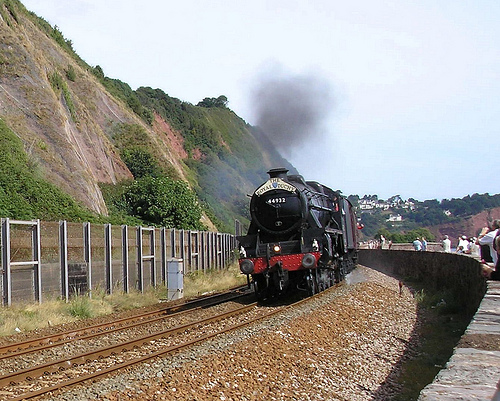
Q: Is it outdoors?
A: Yes, it is outdoors.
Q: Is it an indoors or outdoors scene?
A: It is outdoors.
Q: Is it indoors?
A: No, it is outdoors.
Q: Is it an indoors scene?
A: No, it is outdoors.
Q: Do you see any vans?
A: No, there are no vans.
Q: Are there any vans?
A: No, there are no vans.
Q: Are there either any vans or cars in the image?
A: No, there are no vans or cars.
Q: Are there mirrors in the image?
A: No, there are no mirrors.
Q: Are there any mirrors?
A: No, there are no mirrors.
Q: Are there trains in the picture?
A: Yes, there is a train.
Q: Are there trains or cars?
A: Yes, there is a train.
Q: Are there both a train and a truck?
A: No, there is a train but no trucks.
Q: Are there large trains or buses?
A: Yes, there is a large train.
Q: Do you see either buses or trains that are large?
A: Yes, the train is large.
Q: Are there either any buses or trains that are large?
A: Yes, the train is large.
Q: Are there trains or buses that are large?
A: Yes, the train is large.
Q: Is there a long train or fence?
A: Yes, there is a long train.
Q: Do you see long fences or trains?
A: Yes, there is a long train.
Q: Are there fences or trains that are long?
A: Yes, the train is long.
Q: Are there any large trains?
A: Yes, there is a large train.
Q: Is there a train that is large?
A: Yes, there is a train that is large.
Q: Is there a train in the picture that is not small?
A: Yes, there is a large train.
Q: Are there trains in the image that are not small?
A: Yes, there is a large train.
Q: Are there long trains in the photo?
A: Yes, there is a long train.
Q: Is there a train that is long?
A: Yes, there is a long train.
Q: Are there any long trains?
A: Yes, there is a long train.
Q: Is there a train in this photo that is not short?
A: Yes, there is a long train.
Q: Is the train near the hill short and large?
A: No, the train is large but long.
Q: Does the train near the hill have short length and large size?
A: No, the train is large but long.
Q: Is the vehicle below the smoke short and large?
A: No, the train is large but long.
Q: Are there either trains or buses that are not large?
A: No, there is a train but it is large.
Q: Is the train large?
A: Yes, the train is large.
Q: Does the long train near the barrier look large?
A: Yes, the train is large.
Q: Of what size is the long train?
A: The train is large.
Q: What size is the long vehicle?
A: The train is large.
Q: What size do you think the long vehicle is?
A: The train is large.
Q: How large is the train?
A: The train is large.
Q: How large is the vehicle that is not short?
A: The train is large.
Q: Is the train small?
A: No, the train is large.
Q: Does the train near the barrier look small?
A: No, the train is large.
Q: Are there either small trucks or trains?
A: No, there is a train but it is large.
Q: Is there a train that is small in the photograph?
A: No, there is a train but it is large.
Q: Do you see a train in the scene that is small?
A: No, there is a train but it is large.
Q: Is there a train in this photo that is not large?
A: No, there is a train but it is large.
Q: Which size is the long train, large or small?
A: The train is large.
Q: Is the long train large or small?
A: The train is large.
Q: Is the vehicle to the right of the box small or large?
A: The train is large.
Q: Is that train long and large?
A: Yes, the train is long and large.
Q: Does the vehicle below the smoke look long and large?
A: Yes, the train is long and large.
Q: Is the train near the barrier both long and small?
A: No, the train is long but large.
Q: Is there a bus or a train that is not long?
A: No, there is a train but it is long.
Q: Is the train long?
A: Yes, the train is long.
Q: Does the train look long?
A: Yes, the train is long.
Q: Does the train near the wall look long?
A: Yes, the train is long.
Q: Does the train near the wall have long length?
A: Yes, the train is long.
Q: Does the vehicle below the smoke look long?
A: Yes, the train is long.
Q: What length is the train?
A: The train is long.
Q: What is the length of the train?
A: The train is long.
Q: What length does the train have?
A: The train has long length.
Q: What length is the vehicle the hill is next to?
A: The train is long.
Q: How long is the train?
A: The train is long.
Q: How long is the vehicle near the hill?
A: The train is long.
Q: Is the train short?
A: No, the train is long.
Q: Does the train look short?
A: No, the train is long.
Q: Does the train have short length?
A: No, the train is long.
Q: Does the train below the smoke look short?
A: No, the train is long.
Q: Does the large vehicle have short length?
A: No, the train is long.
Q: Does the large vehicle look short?
A: No, the train is long.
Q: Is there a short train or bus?
A: No, there is a train but it is long.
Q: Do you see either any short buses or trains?
A: No, there is a train but it is long.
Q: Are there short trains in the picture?
A: No, there is a train but it is long.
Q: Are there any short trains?
A: No, there is a train but it is long.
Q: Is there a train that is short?
A: No, there is a train but it is long.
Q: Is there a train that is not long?
A: No, there is a train but it is long.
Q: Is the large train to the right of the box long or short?
A: The train is long.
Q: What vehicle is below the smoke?
A: The vehicle is a train.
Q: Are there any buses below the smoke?
A: No, there is a train below the smoke.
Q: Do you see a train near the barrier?
A: Yes, there is a train near the barrier.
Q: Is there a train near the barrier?
A: Yes, there is a train near the barrier.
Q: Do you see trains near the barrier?
A: Yes, there is a train near the barrier.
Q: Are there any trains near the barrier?
A: Yes, there is a train near the barrier.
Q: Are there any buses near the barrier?
A: No, there is a train near the barrier.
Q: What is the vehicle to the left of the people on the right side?
A: The vehicle is a train.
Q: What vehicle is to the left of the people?
A: The vehicle is a train.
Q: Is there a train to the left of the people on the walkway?
A: Yes, there is a train to the left of the people.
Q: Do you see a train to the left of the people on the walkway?
A: Yes, there is a train to the left of the people.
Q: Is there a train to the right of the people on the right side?
A: No, the train is to the left of the people.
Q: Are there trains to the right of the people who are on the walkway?
A: No, the train is to the left of the people.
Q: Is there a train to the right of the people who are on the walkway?
A: No, the train is to the left of the people.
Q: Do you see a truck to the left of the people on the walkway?
A: No, there is a train to the left of the people.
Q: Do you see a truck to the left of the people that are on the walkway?
A: No, there is a train to the left of the people.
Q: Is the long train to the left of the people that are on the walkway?
A: Yes, the train is to the left of the people.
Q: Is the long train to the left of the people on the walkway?
A: Yes, the train is to the left of the people.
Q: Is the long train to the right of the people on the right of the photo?
A: No, the train is to the left of the people.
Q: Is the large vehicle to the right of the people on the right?
A: No, the train is to the left of the people.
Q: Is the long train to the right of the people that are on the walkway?
A: No, the train is to the left of the people.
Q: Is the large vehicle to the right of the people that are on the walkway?
A: No, the train is to the left of the people.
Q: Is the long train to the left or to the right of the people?
A: The train is to the left of the people.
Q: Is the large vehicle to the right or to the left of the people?
A: The train is to the left of the people.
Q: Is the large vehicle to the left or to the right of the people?
A: The train is to the left of the people.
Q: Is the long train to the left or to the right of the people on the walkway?
A: The train is to the left of the people.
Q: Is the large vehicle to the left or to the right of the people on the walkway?
A: The train is to the left of the people.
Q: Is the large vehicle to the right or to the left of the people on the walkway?
A: The train is to the left of the people.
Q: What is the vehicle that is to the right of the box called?
A: The vehicle is a train.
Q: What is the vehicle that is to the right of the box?
A: The vehicle is a train.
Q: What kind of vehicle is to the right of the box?
A: The vehicle is a train.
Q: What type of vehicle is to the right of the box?
A: The vehicle is a train.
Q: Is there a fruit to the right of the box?
A: No, there is a train to the right of the box.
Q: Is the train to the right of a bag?
A: No, the train is to the right of the box.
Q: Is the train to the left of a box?
A: No, the train is to the right of a box.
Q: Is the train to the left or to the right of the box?
A: The train is to the right of the box.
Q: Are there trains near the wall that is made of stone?
A: Yes, there is a train near the wall.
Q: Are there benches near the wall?
A: No, there is a train near the wall.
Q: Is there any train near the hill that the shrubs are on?
A: Yes, there is a train near the hill.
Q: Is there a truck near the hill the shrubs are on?
A: No, there is a train near the hill.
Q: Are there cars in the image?
A: No, there are no cars.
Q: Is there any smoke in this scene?
A: Yes, there is smoke.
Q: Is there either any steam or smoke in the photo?
A: Yes, there is smoke.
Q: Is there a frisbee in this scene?
A: No, there are no frisbees.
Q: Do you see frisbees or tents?
A: No, there are no frisbees or tents.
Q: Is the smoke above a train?
A: Yes, the smoke is above a train.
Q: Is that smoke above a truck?
A: No, the smoke is above a train.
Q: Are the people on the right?
A: Yes, the people are on the right of the image.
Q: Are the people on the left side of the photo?
A: No, the people are on the right of the image.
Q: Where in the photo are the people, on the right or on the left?
A: The people are on the right of the image.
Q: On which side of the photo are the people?
A: The people are on the right of the image.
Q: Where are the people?
A: The people are on the walkway.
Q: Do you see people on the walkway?
A: Yes, there are people on the walkway.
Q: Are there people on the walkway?
A: Yes, there are people on the walkway.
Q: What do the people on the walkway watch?
A: The people watch the train.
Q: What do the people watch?
A: The people watch the train.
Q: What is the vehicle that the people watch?
A: The vehicle is a train.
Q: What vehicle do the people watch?
A: The people watch the train.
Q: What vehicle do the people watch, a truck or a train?
A: The people watch a train.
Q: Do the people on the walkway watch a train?
A: Yes, the people watch a train.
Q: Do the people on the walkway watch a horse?
A: No, the people watch a train.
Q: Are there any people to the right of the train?
A: Yes, there are people to the right of the train.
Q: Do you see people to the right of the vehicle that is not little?
A: Yes, there are people to the right of the train.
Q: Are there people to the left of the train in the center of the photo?
A: No, the people are to the right of the train.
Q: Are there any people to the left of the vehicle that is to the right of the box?
A: No, the people are to the right of the train.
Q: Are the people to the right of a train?
A: Yes, the people are to the right of a train.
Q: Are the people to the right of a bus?
A: No, the people are to the right of a train.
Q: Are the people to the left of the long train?
A: No, the people are to the right of the train.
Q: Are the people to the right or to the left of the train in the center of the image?
A: The people are to the right of the train.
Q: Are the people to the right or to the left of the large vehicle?
A: The people are to the right of the train.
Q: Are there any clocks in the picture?
A: No, there are no clocks.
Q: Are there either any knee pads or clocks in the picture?
A: No, there are no clocks or knee pads.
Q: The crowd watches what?
A: The crowd watches the train.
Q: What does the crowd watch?
A: The crowd watches the train.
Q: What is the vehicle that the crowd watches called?
A: The vehicle is a train.